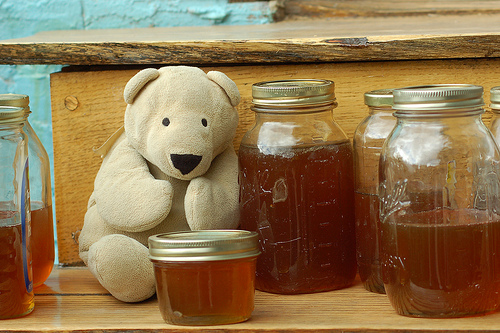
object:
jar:
[144, 225, 268, 326]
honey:
[162, 265, 243, 315]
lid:
[145, 228, 262, 263]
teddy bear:
[74, 64, 247, 306]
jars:
[352, 85, 391, 297]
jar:
[375, 82, 498, 319]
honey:
[393, 227, 498, 313]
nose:
[168, 150, 202, 176]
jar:
[236, 79, 360, 296]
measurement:
[310, 155, 340, 272]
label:
[377, 250, 410, 272]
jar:
[1, 106, 32, 323]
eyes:
[158, 115, 176, 129]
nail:
[60, 93, 83, 113]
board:
[53, 62, 500, 269]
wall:
[3, 2, 254, 24]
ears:
[121, 66, 160, 105]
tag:
[90, 125, 124, 157]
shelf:
[52, 265, 375, 333]